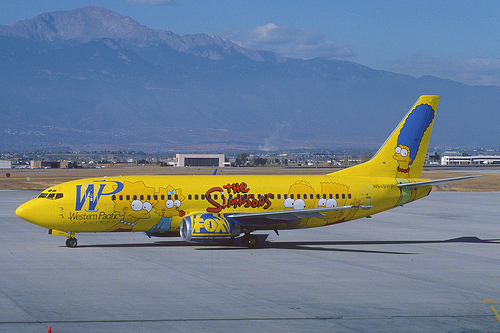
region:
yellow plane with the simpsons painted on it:
[13, 79, 473, 239]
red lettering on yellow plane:
[204, 177, 269, 208]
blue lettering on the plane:
[73, 184, 118, 218]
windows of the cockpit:
[40, 189, 58, 206]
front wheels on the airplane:
[65, 234, 79, 248]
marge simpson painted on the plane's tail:
[386, 105, 423, 201]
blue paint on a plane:
[398, 99, 430, 144]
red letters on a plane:
[204, 175, 273, 213]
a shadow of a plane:
[271, 228, 490, 278]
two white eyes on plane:
[164, 197, 183, 207]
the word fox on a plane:
[191, 213, 236, 238]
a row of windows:
[104, 185, 358, 209]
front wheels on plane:
[63, 228, 82, 255]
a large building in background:
[162, 146, 242, 172]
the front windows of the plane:
[33, 180, 69, 208]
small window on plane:
[110, 194, 118, 200]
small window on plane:
[118, 192, 125, 201]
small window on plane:
[123, 191, 131, 201]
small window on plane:
[131, 192, 137, 201]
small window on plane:
[145, 193, 151, 200]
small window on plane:
[151, 193, 157, 200]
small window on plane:
[159, 192, 166, 200]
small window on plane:
[172, 193, 178, 201]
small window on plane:
[187, 191, 193, 201]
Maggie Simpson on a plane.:
[145, 184, 185, 237]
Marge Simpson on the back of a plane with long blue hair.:
[392, 105, 435, 207]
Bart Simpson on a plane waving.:
[315, 181, 360, 226]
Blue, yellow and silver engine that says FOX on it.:
[179, 213, 241, 244]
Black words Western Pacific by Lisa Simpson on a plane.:
[67, 211, 119, 221]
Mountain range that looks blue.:
[1, 11, 498, 152]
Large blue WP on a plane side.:
[74, 179, 123, 211]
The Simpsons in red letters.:
[204, 181, 273, 213]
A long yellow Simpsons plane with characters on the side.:
[12, 94, 485, 246]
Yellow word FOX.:
[192, 217, 226, 235]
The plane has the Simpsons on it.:
[11, 88, 476, 251]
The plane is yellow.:
[23, 85, 492, 253]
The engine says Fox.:
[178, 210, 244, 238]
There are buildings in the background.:
[171, 145, 237, 170]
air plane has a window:
[111, 194, 116, 201]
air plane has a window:
[126, 193, 128, 198]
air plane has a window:
[132, 194, 137, 199]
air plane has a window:
[140, 192, 143, 200]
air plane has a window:
[145, 193, 151, 199]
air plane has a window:
[153, 194, 158, 200]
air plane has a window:
[160, 192, 166, 199]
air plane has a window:
[173, 194, 180, 200]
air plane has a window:
[194, 194, 200, 199]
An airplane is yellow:
[2, 83, 482, 254]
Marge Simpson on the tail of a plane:
[370, 86, 446, 186]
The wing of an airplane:
[222, 195, 372, 235]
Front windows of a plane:
[26, 182, 66, 207]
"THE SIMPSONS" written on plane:
[196, 171, 281, 216]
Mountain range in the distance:
[0, 0, 496, 155]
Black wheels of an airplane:
[60, 225, 85, 250]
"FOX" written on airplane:
[179, 211, 238, 238]